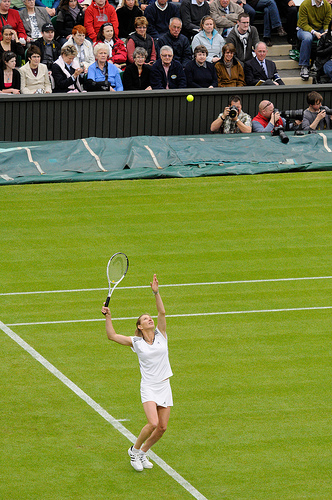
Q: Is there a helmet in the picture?
A: No, there are no helmets.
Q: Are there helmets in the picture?
A: No, there are no helmets.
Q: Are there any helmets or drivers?
A: No, there are no helmets or drivers.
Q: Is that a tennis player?
A: Yes, that is a tennis player.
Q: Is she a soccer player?
A: No, that is a tennis player.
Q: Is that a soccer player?
A: No, that is a tennis player.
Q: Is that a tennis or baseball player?
A: That is a tennis player.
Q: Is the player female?
A: Yes, the player is female.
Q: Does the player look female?
A: Yes, the player is female.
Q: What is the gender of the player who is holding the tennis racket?
A: The player is female.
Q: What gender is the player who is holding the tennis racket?
A: The player is female.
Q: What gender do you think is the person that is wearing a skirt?
A: The player is female.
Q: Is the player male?
A: No, the player is female.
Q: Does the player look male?
A: No, the player is female.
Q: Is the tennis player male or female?
A: The player is female.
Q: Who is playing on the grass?
A: The player is playing on the grass.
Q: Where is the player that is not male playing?
A: The player is playing on the grass.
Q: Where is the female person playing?
A: The player is playing on the grass.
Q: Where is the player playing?
A: The player is playing on the grass.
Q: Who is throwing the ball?
A: The player is throwing the ball.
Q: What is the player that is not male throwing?
A: The player is throwing the ball.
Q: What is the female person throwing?
A: The player is throwing the ball.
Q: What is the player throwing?
A: The player is throwing the ball.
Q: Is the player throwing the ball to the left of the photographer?
A: Yes, the player is throwing the ball.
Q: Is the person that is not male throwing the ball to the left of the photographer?
A: Yes, the player is throwing the ball.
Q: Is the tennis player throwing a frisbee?
A: No, the player is throwing the ball.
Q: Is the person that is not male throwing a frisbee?
A: No, the player is throwing the ball.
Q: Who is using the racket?
A: The player is using the racket.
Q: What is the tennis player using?
A: The player is using a racket.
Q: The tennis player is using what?
A: The player is using a racket.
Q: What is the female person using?
A: The player is using a racket.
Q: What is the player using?
A: The player is using a racket.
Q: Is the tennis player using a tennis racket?
A: Yes, the player is using a tennis racket.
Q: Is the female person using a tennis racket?
A: Yes, the player is using a tennis racket.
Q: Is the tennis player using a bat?
A: No, the player is using a tennis racket.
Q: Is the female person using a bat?
A: No, the player is using a tennis racket.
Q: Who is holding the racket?
A: The player is holding the racket.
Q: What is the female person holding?
A: The player is holding the tennis racket.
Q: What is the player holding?
A: The player is holding the tennis racket.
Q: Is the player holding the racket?
A: Yes, the player is holding the racket.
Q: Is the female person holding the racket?
A: Yes, the player is holding the racket.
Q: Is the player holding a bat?
A: No, the player is holding the racket.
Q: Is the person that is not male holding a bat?
A: No, the player is holding the racket.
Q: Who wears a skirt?
A: The player wears a skirt.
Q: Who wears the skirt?
A: The player wears a skirt.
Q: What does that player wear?
A: The player wears a skirt.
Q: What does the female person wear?
A: The player wears a skirt.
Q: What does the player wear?
A: The player wears a skirt.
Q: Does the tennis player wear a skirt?
A: Yes, the player wears a skirt.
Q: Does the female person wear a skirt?
A: Yes, the player wears a skirt.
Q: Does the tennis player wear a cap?
A: No, the player wears a skirt.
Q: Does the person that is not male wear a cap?
A: No, the player wears a skirt.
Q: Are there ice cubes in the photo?
A: No, there are no ice cubes.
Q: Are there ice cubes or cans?
A: No, there are no ice cubes or cans.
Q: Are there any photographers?
A: Yes, there is a photographer.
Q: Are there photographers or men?
A: Yes, there is a photographer.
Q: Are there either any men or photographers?
A: Yes, there is a photographer.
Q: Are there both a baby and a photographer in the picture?
A: No, there is a photographer but no babies.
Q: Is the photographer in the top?
A: Yes, the photographer is in the top of the image.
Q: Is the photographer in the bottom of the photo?
A: No, the photographer is in the top of the image.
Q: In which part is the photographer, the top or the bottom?
A: The photographer is in the top of the image.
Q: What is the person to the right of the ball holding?
A: The photographer is holding the camera.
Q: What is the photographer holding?
A: The photographer is holding the camera.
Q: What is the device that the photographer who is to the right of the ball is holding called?
A: The device is a camera.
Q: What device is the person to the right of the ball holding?
A: The photographer is holding the camera.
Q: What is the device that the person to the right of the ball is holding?
A: The device is a camera.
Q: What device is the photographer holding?
A: The photographer is holding the camera.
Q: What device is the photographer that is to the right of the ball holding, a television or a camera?
A: The photographer is holding a camera.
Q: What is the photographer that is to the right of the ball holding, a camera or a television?
A: The photographer is holding a camera.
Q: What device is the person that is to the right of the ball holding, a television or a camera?
A: The photographer is holding a camera.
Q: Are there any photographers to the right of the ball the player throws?
A: Yes, there is a photographer to the right of the ball.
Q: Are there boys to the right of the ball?
A: No, there is a photographer to the right of the ball.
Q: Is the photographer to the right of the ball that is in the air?
A: Yes, the photographer is to the right of the ball.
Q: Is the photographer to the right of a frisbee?
A: No, the photographer is to the right of the ball.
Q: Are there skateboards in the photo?
A: No, there are no skateboards.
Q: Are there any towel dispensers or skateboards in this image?
A: No, there are no skateboards or towel dispensers.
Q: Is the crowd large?
A: Yes, the crowd is large.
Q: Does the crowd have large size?
A: Yes, the crowd is large.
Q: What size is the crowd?
A: The crowd is large.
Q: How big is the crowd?
A: The crowd is large.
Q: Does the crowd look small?
A: No, the crowd is large.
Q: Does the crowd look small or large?
A: The crowd is large.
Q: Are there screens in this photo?
A: No, there are no screens.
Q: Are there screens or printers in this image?
A: No, there are no screens or printers.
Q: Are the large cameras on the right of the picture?
A: Yes, the cameras are on the right of the image.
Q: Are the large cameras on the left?
A: No, the cameras are on the right of the image.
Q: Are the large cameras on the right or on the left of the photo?
A: The cameras are on the right of the image.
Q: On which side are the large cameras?
A: The cameras are on the right of the image.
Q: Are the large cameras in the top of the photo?
A: Yes, the cameras are in the top of the image.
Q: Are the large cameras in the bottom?
A: No, the cameras are in the top of the image.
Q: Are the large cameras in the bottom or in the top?
A: The cameras are in the top of the image.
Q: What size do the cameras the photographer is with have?
A: The cameras have large size.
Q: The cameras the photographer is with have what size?
A: The cameras are large.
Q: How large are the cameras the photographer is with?
A: The cameras are large.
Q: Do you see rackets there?
A: Yes, there is a racket.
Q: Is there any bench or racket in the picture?
A: Yes, there is a racket.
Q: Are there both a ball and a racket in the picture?
A: Yes, there are both a racket and a ball.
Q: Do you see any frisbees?
A: No, there are no frisbees.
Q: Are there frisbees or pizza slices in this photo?
A: No, there are no frisbees or pizza slices.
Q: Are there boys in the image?
A: No, there are no boys.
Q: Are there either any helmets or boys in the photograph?
A: No, there are no boys or helmets.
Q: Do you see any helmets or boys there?
A: No, there are no boys or helmets.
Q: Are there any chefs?
A: No, there are no chefs.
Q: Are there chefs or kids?
A: No, there are no chefs or kids.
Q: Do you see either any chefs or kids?
A: No, there are no chefs or kids.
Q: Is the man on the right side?
A: Yes, the man is on the right of the image.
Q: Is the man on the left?
A: No, the man is on the right of the image.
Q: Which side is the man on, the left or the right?
A: The man is on the right of the image.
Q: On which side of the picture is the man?
A: The man is on the right of the image.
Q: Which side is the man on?
A: The man is on the right of the image.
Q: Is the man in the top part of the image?
A: Yes, the man is in the top of the image.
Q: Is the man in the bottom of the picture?
A: No, the man is in the top of the image.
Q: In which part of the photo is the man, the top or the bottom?
A: The man is in the top of the image.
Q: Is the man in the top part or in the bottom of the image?
A: The man is in the top of the image.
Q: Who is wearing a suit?
A: The man is wearing a suit.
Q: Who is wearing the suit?
A: The man is wearing a suit.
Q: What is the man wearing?
A: The man is wearing a suit.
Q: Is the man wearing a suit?
A: Yes, the man is wearing a suit.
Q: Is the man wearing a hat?
A: No, the man is wearing a suit.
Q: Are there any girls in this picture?
A: No, there are no girls.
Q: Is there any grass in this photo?
A: Yes, there is grass.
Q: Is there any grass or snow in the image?
A: Yes, there is grass.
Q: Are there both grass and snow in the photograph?
A: No, there is grass but no snow.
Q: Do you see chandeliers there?
A: No, there are no chandeliers.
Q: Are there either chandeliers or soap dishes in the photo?
A: No, there are no chandeliers or soap dishes.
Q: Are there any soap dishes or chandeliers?
A: No, there are no chandeliers or soap dishes.